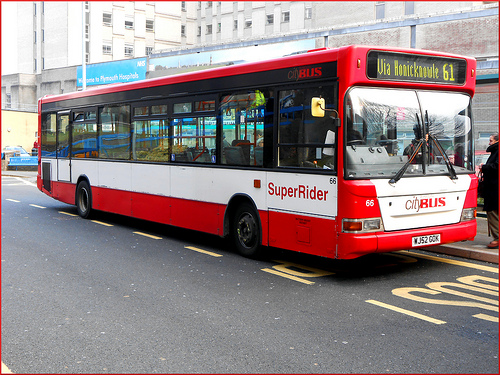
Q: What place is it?
A: It is a street.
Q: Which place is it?
A: It is a street.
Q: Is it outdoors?
A: Yes, it is outdoors.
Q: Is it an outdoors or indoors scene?
A: It is outdoors.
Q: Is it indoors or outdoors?
A: It is outdoors.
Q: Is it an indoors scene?
A: No, it is outdoors.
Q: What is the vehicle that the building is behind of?
A: The vehicle is a bus.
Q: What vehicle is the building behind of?
A: The building is behind the bus.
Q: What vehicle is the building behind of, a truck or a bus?
A: The building is behind a bus.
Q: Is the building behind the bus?
A: Yes, the building is behind the bus.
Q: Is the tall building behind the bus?
A: Yes, the building is behind the bus.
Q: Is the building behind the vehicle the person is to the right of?
A: Yes, the building is behind the bus.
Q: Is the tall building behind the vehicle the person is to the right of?
A: Yes, the building is behind the bus.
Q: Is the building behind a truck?
A: No, the building is behind the bus.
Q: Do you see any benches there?
A: Yes, there is a bench.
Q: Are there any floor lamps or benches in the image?
A: Yes, there is a bench.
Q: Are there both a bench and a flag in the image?
A: No, there is a bench but no flags.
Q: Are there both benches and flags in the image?
A: No, there is a bench but no flags.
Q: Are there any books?
A: No, there are no books.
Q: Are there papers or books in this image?
A: No, there are no books or papers.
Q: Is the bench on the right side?
A: No, the bench is on the left of the image.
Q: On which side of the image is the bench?
A: The bench is on the left of the image.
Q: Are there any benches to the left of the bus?
A: Yes, there is a bench to the left of the bus.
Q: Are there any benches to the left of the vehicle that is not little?
A: Yes, there is a bench to the left of the bus.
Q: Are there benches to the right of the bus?
A: No, the bench is to the left of the bus.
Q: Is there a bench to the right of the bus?
A: No, the bench is to the left of the bus.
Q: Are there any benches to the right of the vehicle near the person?
A: No, the bench is to the left of the bus.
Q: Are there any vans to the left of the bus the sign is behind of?
A: No, there is a bench to the left of the bus.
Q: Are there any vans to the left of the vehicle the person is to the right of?
A: No, there is a bench to the left of the bus.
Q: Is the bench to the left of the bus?
A: Yes, the bench is to the left of the bus.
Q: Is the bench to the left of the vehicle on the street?
A: Yes, the bench is to the left of the bus.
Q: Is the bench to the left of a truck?
A: No, the bench is to the left of the bus.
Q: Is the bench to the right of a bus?
A: No, the bench is to the left of a bus.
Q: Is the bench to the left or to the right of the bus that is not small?
A: The bench is to the left of the bus.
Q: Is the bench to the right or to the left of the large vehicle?
A: The bench is to the left of the bus.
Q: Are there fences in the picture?
A: No, there are no fences.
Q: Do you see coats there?
A: Yes, there is a coat.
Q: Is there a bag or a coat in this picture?
A: Yes, there is a coat.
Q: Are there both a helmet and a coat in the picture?
A: No, there is a coat but no helmets.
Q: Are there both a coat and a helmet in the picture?
A: No, there is a coat but no helmets.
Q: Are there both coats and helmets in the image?
A: No, there is a coat but no helmets.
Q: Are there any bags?
A: No, there are no bags.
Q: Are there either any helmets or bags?
A: No, there are no bags or helmets.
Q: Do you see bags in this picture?
A: No, there are no bags.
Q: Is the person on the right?
A: Yes, the person is on the right of the image.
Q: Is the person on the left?
A: No, the person is on the right of the image.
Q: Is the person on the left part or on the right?
A: The person is on the right of the image.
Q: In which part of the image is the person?
A: The person is on the right of the image.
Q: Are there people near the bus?
A: Yes, there is a person near the bus.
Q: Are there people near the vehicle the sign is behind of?
A: Yes, there is a person near the bus.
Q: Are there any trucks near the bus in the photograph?
A: No, there is a person near the bus.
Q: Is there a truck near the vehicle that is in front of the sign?
A: No, there is a person near the bus.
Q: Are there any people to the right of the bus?
A: Yes, there is a person to the right of the bus.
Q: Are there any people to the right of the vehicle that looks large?
A: Yes, there is a person to the right of the bus.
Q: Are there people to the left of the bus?
A: No, the person is to the right of the bus.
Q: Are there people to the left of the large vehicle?
A: No, the person is to the right of the bus.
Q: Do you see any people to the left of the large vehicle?
A: No, the person is to the right of the bus.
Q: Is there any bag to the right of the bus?
A: No, there is a person to the right of the bus.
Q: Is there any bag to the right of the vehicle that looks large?
A: No, there is a person to the right of the bus.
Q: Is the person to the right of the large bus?
A: Yes, the person is to the right of the bus.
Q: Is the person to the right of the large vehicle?
A: Yes, the person is to the right of the bus.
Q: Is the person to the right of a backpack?
A: No, the person is to the right of the bus.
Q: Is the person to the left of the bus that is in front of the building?
A: No, the person is to the right of the bus.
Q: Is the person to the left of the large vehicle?
A: No, the person is to the right of the bus.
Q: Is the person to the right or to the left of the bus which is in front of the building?
A: The person is to the right of the bus.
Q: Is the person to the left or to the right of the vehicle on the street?
A: The person is to the right of the bus.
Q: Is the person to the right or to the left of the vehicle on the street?
A: The person is to the right of the bus.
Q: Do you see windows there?
A: Yes, there is a window.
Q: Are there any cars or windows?
A: Yes, there is a window.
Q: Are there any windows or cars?
A: Yes, there is a window.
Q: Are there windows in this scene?
A: Yes, there is a window.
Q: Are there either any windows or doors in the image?
A: Yes, there is a window.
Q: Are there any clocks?
A: No, there are no clocks.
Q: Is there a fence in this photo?
A: No, there are no fences.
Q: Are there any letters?
A: Yes, there are letters.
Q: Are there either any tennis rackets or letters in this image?
A: Yes, there are letters.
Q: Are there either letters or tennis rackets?
A: Yes, there are letters.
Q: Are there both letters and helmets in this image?
A: No, there are letters but no helmets.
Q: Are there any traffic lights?
A: No, there are no traffic lights.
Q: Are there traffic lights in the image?
A: No, there are no traffic lights.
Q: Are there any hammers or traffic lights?
A: No, there are no traffic lights or hammers.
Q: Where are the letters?
A: The letters are on the street.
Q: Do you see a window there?
A: Yes, there is a window.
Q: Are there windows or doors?
A: Yes, there is a window.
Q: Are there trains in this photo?
A: No, there are no trains.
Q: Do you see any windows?
A: Yes, there is a window.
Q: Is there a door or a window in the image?
A: Yes, there is a window.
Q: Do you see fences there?
A: No, there are no fences.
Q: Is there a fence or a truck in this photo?
A: No, there are no fences or trucks.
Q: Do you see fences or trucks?
A: No, there are no fences or trucks.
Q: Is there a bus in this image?
A: Yes, there is a bus.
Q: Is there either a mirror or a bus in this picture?
A: Yes, there is a bus.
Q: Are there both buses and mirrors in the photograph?
A: Yes, there are both a bus and a mirror.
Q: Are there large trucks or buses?
A: Yes, there is a large bus.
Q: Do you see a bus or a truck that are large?
A: Yes, the bus is large.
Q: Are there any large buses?
A: Yes, there is a large bus.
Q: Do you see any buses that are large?
A: Yes, there is a bus that is large.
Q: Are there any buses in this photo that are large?
A: Yes, there is a bus that is large.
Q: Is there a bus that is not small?
A: Yes, there is a large bus.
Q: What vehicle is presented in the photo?
A: The vehicle is a bus.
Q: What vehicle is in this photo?
A: The vehicle is a bus.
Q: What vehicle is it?
A: The vehicle is a bus.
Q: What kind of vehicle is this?
A: That is a bus.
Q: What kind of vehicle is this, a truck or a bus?
A: That is a bus.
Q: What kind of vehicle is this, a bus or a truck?
A: That is a bus.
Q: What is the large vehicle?
A: The vehicle is a bus.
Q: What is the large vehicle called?
A: The vehicle is a bus.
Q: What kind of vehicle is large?
A: The vehicle is a bus.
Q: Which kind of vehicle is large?
A: The vehicle is a bus.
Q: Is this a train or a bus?
A: This is a bus.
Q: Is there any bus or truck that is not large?
A: No, there is a bus but it is large.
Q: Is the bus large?
A: Yes, the bus is large.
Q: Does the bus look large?
A: Yes, the bus is large.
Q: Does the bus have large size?
A: Yes, the bus is large.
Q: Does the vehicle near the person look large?
A: Yes, the bus is large.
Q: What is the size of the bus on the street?
A: The bus is large.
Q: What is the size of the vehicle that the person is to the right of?
A: The bus is large.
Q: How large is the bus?
A: The bus is large.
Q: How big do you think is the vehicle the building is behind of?
A: The bus is large.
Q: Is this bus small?
A: No, the bus is large.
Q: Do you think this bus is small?
A: No, the bus is large.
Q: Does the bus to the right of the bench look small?
A: No, the bus is large.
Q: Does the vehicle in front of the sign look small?
A: No, the bus is large.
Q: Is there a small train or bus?
A: No, there is a bus but it is large.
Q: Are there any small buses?
A: No, there is a bus but it is large.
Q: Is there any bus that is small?
A: No, there is a bus but it is large.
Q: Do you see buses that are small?
A: No, there is a bus but it is large.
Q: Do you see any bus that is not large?
A: No, there is a bus but it is large.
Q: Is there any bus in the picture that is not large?
A: No, there is a bus but it is large.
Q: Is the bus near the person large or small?
A: The bus is large.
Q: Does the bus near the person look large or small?
A: The bus is large.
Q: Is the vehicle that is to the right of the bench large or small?
A: The bus is large.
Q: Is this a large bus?
A: Yes, this is a large bus.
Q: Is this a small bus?
A: No, this is a large bus.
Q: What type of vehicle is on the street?
A: The vehicle is a bus.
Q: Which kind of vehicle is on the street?
A: The vehicle is a bus.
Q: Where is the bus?
A: The bus is on the street.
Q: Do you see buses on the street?
A: Yes, there is a bus on the street.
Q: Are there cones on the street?
A: No, there is a bus on the street.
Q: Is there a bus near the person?
A: Yes, there is a bus near the person.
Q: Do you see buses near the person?
A: Yes, there is a bus near the person.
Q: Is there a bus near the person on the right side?
A: Yes, there is a bus near the person.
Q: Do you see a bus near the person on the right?
A: Yes, there is a bus near the person.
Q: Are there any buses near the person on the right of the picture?
A: Yes, there is a bus near the person.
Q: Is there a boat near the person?
A: No, there is a bus near the person.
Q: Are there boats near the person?
A: No, there is a bus near the person.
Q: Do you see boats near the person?
A: No, there is a bus near the person.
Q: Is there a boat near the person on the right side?
A: No, there is a bus near the person.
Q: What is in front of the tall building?
A: The bus is in front of the building.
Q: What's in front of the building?
A: The bus is in front of the building.